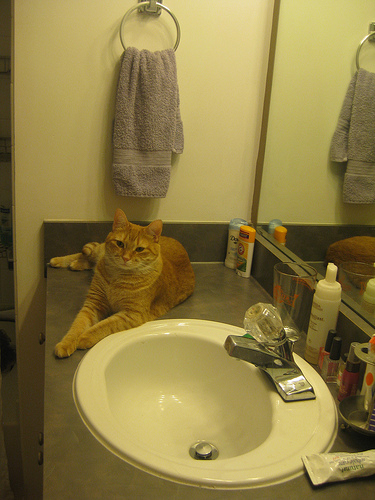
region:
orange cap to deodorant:
[235, 224, 255, 238]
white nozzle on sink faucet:
[242, 300, 283, 341]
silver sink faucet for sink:
[226, 341, 280, 366]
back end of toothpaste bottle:
[303, 450, 373, 483]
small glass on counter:
[272, 250, 313, 319]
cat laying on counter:
[33, 213, 190, 372]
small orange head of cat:
[101, 208, 163, 272]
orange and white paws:
[52, 295, 136, 364]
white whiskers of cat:
[127, 258, 154, 274]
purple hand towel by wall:
[106, 40, 187, 200]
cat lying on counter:
[49, 208, 195, 356]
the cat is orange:
[50, 208, 195, 357]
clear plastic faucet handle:
[243, 302, 282, 340]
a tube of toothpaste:
[302, 448, 373, 483]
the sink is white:
[74, 318, 335, 485]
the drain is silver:
[189, 441, 217, 461]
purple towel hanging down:
[111, 47, 183, 196]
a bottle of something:
[303, 264, 340, 363]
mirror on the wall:
[256, 4, 373, 316]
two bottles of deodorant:
[222, 218, 253, 276]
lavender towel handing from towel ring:
[114, 40, 187, 200]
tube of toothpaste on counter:
[304, 430, 364, 486]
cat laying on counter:
[50, 208, 205, 347]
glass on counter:
[270, 254, 303, 342]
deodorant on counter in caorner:
[220, 212, 256, 276]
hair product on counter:
[302, 255, 337, 371]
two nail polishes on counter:
[316, 322, 341, 378]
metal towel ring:
[117, 0, 191, 58]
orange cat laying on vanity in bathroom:
[43, 206, 311, 439]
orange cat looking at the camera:
[86, 206, 176, 326]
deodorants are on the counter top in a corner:
[222, 214, 256, 279]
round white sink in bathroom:
[81, 320, 333, 485]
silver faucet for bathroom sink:
[215, 300, 317, 405]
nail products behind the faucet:
[314, 326, 363, 406]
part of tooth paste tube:
[301, 452, 374, 481]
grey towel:
[105, 46, 182, 201]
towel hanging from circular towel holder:
[112, 1, 180, 199]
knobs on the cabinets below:
[27, 326, 53, 466]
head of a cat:
[98, 192, 179, 283]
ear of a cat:
[147, 216, 165, 240]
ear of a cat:
[109, 206, 131, 227]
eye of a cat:
[116, 235, 128, 250]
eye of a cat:
[140, 241, 150, 254]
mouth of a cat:
[114, 250, 145, 275]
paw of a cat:
[45, 336, 85, 362]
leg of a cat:
[48, 235, 95, 286]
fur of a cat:
[109, 264, 148, 301]